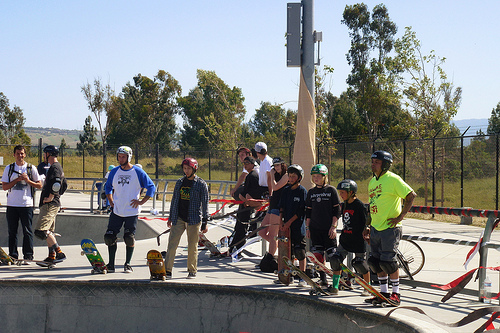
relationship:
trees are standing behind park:
[0, 4, 498, 177] [2, 145, 498, 333]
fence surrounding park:
[1, 137, 499, 219] [2, 145, 498, 333]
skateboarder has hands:
[101, 143, 159, 273] [109, 197, 140, 208]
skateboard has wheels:
[79, 235, 109, 274] [81, 250, 97, 258]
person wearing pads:
[33, 146, 70, 271] [51, 179, 61, 196]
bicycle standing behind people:
[364, 231, 427, 280] [360, 148, 418, 309]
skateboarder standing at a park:
[101, 143, 159, 273] [2, 145, 498, 333]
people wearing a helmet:
[360, 148, 418, 309] [369, 149, 393, 163]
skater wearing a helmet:
[162, 158, 208, 278] [182, 157, 200, 171]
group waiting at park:
[5, 138, 413, 306] [2, 145, 498, 333]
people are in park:
[2, 142, 418, 310] [2, 145, 498, 333]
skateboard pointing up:
[79, 235, 109, 274] [78, 231, 95, 239]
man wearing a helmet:
[99, 145, 159, 272] [115, 145, 134, 160]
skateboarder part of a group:
[101, 143, 159, 273] [5, 138, 413, 306]